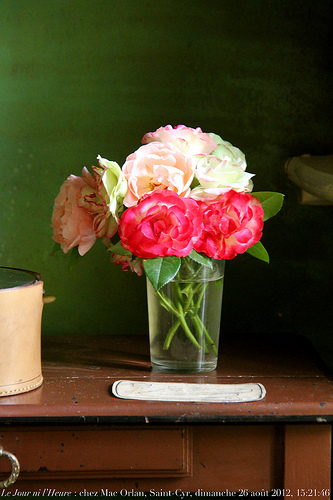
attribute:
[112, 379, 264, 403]
dish — white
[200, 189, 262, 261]
flower — hot pink, pink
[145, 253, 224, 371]
cup — glass, clear, filled with water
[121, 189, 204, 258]
flower — hot pink, fresh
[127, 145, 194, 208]
flower — light pink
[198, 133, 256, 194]
flower — white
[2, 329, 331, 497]
desk — wooden, brown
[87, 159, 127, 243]
flower — green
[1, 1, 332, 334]
wall — green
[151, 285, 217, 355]
stems — green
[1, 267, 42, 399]
container — pink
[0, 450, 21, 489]
handle — silver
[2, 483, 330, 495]
copywrite — white